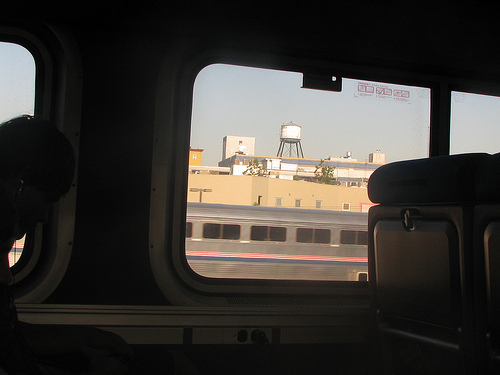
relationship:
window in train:
[200, 68, 230, 85] [92, 6, 472, 59]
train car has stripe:
[196, 210, 359, 223] [210, 252, 272, 256]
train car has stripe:
[196, 210, 359, 223] [273, 261, 325, 266]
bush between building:
[317, 167, 341, 182] [270, 180, 354, 200]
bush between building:
[249, 167, 269, 176] [211, 179, 246, 198]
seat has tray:
[376, 164, 481, 190] [381, 235, 437, 316]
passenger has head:
[0, 110, 132, 367] [3, 127, 73, 202]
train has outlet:
[92, 6, 472, 59] [223, 327, 275, 345]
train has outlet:
[92, 6, 472, 59] [252, 328, 268, 343]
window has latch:
[200, 68, 230, 85] [308, 75, 340, 90]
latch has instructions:
[308, 75, 340, 90] [360, 86, 405, 98]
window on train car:
[188, 222, 193, 240] [196, 210, 359, 223]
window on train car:
[207, 224, 220, 237] [196, 210, 359, 223]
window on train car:
[225, 228, 241, 238] [196, 210, 359, 223]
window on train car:
[256, 228, 266, 238] [196, 210, 359, 223]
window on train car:
[271, 231, 288, 237] [196, 210, 359, 223]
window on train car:
[301, 234, 312, 242] [196, 210, 359, 223]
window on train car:
[319, 235, 331, 243] [196, 210, 359, 223]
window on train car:
[346, 234, 356, 242] [196, 210, 359, 223]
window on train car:
[359, 235, 369, 243] [196, 210, 359, 223]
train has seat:
[92, 6, 472, 59] [376, 164, 481, 190]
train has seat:
[92, 6, 472, 59] [484, 166, 499, 195]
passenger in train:
[0, 110, 132, 367] [92, 6, 472, 59]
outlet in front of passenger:
[223, 327, 275, 345] [0, 110, 132, 367]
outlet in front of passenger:
[252, 328, 268, 343] [0, 110, 132, 367]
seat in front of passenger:
[376, 164, 481, 190] [0, 110, 132, 367]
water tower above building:
[276, 118, 307, 156] [270, 180, 354, 200]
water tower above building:
[276, 118, 307, 156] [211, 179, 246, 198]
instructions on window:
[360, 86, 405, 98] [200, 68, 230, 85]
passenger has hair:
[0, 110, 132, 367] [8, 119, 32, 126]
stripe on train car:
[210, 252, 272, 256] [196, 210, 359, 223]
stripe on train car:
[273, 261, 325, 266] [196, 210, 359, 223]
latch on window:
[299, 72, 343, 93] [158, 39, 445, 282]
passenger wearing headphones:
[3, 110, 88, 323] [7, 148, 35, 212]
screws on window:
[143, 78, 163, 278] [149, 41, 424, 303]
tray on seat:
[358, 206, 471, 346] [337, 152, 497, 372]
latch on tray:
[404, 208, 417, 227] [358, 206, 471, 346]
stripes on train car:
[185, 242, 387, 269] [185, 200, 369, 279]